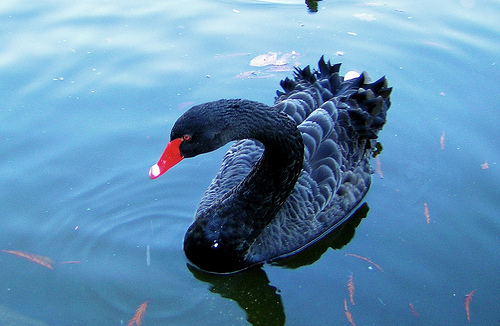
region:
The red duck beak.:
[150, 146, 187, 181]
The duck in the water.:
[139, 68, 399, 292]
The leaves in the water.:
[332, 268, 377, 324]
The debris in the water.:
[247, 39, 294, 79]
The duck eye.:
[180, 128, 195, 142]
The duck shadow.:
[205, 272, 303, 324]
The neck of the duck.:
[234, 95, 306, 243]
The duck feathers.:
[330, 73, 388, 134]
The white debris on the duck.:
[208, 239, 230, 254]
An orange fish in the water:
[122, 292, 151, 324]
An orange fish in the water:
[462, 283, 481, 319]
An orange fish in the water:
[420, 199, 432, 221]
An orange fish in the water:
[437, 128, 447, 151]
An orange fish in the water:
[346, 267, 356, 302]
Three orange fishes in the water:
[341, 248, 382, 323]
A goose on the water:
[143, 53, 394, 271]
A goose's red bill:
[146, 135, 186, 177]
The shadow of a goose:
[185, 197, 371, 322]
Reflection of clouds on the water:
[0, 1, 497, 99]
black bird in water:
[108, 73, 405, 188]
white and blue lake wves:
[4, 22, 59, 77]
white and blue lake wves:
[395, 218, 409, 226]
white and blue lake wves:
[365, 216, 422, 243]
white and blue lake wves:
[412, 162, 484, 203]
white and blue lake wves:
[21, 179, 75, 210]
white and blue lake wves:
[378, 73, 438, 104]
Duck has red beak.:
[144, 158, 177, 178]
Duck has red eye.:
[176, 129, 198, 153]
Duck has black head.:
[181, 108, 212, 125]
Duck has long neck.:
[240, 122, 295, 227]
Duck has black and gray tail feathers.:
[303, 59, 398, 134]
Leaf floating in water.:
[411, 203, 433, 228]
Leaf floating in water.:
[12, 245, 82, 285]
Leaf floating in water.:
[111, 303, 175, 324]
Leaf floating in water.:
[424, 127, 454, 152]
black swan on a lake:
[146, 62, 388, 284]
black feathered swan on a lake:
[146, 62, 388, 265]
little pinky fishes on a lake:
[4, 137, 488, 324]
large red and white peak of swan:
[148, 138, 185, 180]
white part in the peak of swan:
[149, 162, 159, 177]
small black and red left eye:
[179, 129, 192, 143]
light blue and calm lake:
[0, 3, 495, 320]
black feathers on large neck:
[179, 98, 301, 265]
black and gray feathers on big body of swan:
[206, 64, 388, 253]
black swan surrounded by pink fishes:
[146, 54, 389, 281]